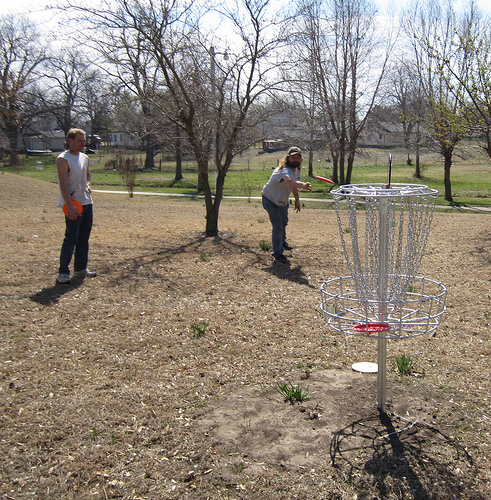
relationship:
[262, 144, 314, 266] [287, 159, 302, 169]
guy has beard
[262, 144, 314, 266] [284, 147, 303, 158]
guy wearing hat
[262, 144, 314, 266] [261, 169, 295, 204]
guy wearing tshirt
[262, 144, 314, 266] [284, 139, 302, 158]
guy wearing hat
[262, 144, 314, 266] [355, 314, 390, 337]
guy playing frisbee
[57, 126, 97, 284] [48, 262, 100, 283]
man wearing shoes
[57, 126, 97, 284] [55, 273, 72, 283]
man wearing shoes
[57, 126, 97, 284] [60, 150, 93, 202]
man wearing shirt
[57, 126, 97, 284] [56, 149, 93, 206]
man wearing shirt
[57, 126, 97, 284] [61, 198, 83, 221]
man holding frisbee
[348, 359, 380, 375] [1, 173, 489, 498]
disk on ground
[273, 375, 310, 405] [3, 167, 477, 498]
grass in dirt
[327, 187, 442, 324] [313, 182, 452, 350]
chains hanging down into container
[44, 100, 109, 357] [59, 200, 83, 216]
man holding frisbee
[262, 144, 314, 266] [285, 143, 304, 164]
guy wearing a hat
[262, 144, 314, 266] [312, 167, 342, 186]
guy throwing disk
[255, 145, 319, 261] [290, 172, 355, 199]
guy throwing orange frisbee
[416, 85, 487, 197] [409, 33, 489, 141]
tree with leaves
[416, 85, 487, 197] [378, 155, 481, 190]
tree standing in grass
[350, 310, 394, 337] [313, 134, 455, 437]
frisbee in frisbee catcher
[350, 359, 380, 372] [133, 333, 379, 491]
disk on ground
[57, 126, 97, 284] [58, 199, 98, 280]
man wearing jeans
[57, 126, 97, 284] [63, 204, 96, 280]
man wearing blue jeans